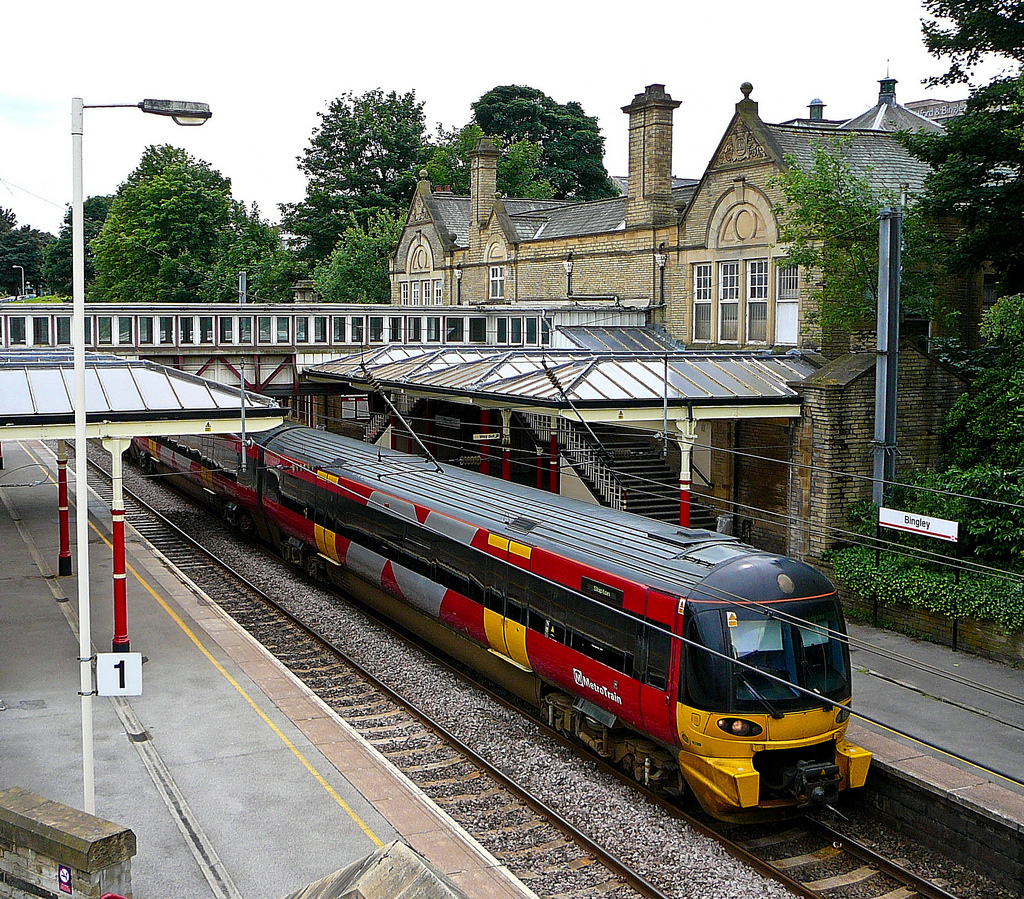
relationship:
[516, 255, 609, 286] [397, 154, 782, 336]
wall on side of a building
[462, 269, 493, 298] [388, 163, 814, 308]
wall on side of a building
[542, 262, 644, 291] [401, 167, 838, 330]
wall on side of a building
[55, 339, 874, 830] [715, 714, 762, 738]
train has a headlight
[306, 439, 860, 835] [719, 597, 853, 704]
train has a window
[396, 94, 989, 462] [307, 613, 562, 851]
building next to tracks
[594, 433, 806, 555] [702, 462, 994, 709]
stairs to platform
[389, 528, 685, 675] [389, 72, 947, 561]
windows on building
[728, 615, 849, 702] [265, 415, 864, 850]
windows of train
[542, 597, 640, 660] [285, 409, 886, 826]
window of train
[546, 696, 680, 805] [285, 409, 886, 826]
wheels of train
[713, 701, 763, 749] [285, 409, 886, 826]
headlight of train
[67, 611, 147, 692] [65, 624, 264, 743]
1 on sign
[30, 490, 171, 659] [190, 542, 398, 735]
poles by tracks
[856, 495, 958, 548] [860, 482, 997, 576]
writing on sign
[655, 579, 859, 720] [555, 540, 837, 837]
windows on train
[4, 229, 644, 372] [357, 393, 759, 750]
bridge across train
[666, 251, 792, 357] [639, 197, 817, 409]
windows on building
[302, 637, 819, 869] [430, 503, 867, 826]
tracks under train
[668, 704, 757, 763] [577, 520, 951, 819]
headlight on train